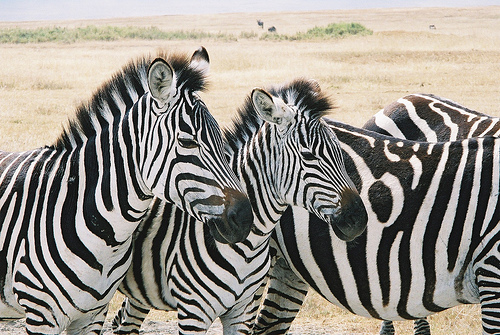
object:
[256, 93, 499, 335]
zebra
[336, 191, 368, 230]
snout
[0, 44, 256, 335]
animal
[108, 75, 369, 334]
animal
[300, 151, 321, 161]
eye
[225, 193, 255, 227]
nose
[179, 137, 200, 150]
eye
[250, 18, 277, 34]
animals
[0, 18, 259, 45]
shrubs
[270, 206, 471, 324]
belly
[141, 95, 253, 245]
face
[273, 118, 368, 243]
face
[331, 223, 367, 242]
mouth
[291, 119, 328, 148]
skin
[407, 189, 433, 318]
skin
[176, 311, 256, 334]
legs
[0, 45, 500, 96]
sand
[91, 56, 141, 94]
hair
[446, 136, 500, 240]
stripes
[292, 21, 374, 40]
bushes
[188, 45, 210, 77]
ears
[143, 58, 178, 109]
ear